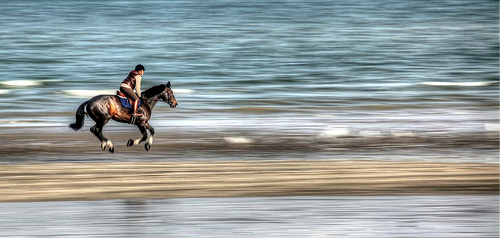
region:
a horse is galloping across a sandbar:
[65, 60, 233, 198]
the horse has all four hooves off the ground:
[92, 132, 159, 171]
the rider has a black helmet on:
[132, 60, 144, 71]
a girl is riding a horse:
[113, 63, 148, 123]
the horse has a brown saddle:
[113, 88, 146, 118]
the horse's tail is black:
[65, 95, 90, 130]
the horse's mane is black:
[140, 78, 165, 99]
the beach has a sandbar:
[2, 83, 497, 216]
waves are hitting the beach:
[2, 60, 494, 145]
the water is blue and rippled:
[5, 1, 499, 68]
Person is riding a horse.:
[82, 52, 187, 130]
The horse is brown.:
[148, 85, 185, 117]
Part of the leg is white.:
[97, 132, 153, 155]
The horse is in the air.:
[88, 131, 178, 155]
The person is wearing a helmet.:
[117, 55, 152, 74]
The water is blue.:
[184, 41, 246, 71]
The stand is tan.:
[148, 164, 197, 182]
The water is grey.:
[270, 203, 332, 224]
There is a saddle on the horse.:
[105, 93, 142, 108]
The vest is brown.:
[113, 68, 152, 92]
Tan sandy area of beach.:
[202, 144, 415, 205]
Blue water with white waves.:
[203, 95, 408, 164]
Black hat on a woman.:
[130, 59, 152, 79]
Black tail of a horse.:
[59, 85, 87, 149]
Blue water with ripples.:
[243, 19, 434, 115]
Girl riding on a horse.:
[101, 44, 173, 129]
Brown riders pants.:
[108, 85, 147, 110]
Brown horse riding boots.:
[112, 95, 149, 131]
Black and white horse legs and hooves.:
[74, 125, 172, 160]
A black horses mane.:
[142, 69, 169, 112]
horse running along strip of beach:
[51, 50, 281, 206]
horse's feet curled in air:
[87, 116, 167, 166]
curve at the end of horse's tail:
[55, 65, 195, 165]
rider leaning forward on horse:
[95, 50, 190, 170]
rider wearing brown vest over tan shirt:
[105, 55, 150, 105]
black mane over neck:
[125, 50, 185, 110]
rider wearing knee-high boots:
[110, 85, 150, 120]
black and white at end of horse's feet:
[80, 120, 170, 160]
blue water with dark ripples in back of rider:
[85, 30, 285, 90]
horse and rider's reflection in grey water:
[105, 191, 215, 231]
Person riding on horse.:
[48, 24, 203, 204]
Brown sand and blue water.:
[184, 155, 469, 230]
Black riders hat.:
[124, 44, 159, 76]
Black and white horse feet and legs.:
[81, 123, 166, 166]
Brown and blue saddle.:
[102, 90, 144, 112]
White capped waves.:
[179, 107, 386, 177]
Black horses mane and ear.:
[143, 68, 187, 132]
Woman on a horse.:
[105, 49, 162, 127]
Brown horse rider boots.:
[115, 97, 149, 131]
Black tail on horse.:
[51, 87, 101, 159]